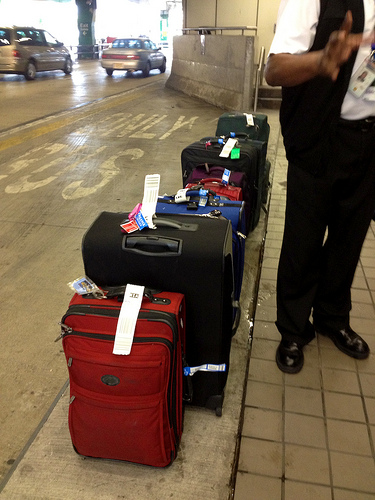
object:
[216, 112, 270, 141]
green luggage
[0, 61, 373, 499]
sidewalk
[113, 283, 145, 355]
tag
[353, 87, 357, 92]
badge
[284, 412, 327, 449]
square tile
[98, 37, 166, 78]
car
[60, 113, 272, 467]
dumb bell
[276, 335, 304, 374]
black shoe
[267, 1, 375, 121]
shirt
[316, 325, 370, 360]
shoe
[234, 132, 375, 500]
floor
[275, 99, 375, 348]
pants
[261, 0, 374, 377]
man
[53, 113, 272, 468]
luggage